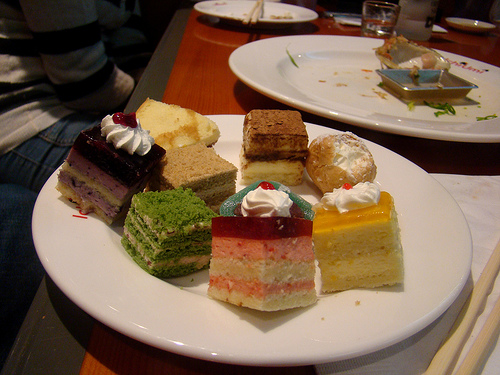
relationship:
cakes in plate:
[54, 97, 404, 312] [23, 99, 483, 366]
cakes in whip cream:
[54, 97, 404, 312] [237, 179, 295, 217]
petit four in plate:
[156, 142, 238, 219] [23, 99, 483, 366]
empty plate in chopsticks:
[195, 0, 317, 22] [241, 0, 263, 25]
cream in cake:
[237, 186, 294, 217] [207, 182, 317, 313]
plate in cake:
[23, 99, 483, 366] [313, 188, 405, 291]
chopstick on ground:
[422, 241, 499, 375] [162, 0, 500, 176]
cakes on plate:
[54, 97, 404, 312] [23, 99, 483, 366]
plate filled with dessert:
[23, 99, 483, 366] [55, 123, 166, 225]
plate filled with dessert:
[23, 99, 483, 366] [120, 186, 220, 277]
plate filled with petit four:
[23, 99, 483, 366] [199, 184, 320, 309]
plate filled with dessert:
[23, 99, 483, 366] [310, 191, 405, 293]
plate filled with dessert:
[23, 99, 483, 366] [239, 109, 308, 186]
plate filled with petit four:
[23, 99, 483, 366] [156, 142, 238, 219]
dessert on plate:
[120, 186, 220, 277] [23, 99, 483, 366]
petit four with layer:
[199, 184, 320, 309] [204, 289, 320, 310]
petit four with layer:
[199, 184, 320, 309] [206, 270, 317, 293]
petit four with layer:
[199, 184, 320, 309] [206, 251, 319, 282]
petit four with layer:
[199, 184, 320, 309] [206, 234, 314, 257]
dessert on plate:
[55, 123, 166, 225] [23, 99, 483, 366]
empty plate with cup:
[228, 35, 500, 143] [392, 68, 475, 98]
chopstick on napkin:
[422, 238, 498, 372] [312, 174, 499, 374]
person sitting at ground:
[1, 0, 148, 210] [162, 0, 500, 176]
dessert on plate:
[57, 107, 163, 227] [23, 99, 483, 366]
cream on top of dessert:
[100, 114, 152, 155] [57, 107, 163, 227]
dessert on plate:
[115, 178, 221, 284] [23, 99, 483, 366]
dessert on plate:
[348, 207, 390, 283] [23, 99, 483, 366]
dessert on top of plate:
[306, 132, 386, 199] [381, 135, 498, 333]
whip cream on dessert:
[321, 181, 379, 215] [314, 189, 403, 295]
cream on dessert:
[240, 186, 294, 217] [210, 214, 317, 314]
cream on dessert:
[100, 114, 155, 156] [57, 107, 163, 227]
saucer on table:
[450, 14, 484, 37] [173, 19, 232, 109]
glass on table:
[351, 9, 402, 36] [174, 32, 229, 111]